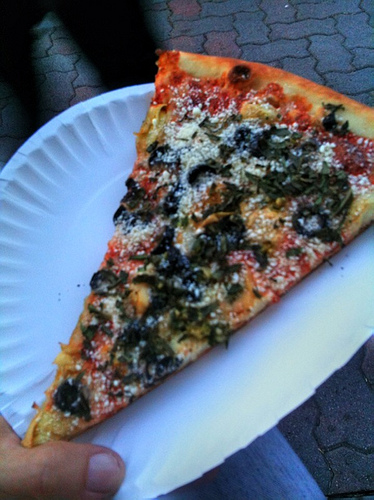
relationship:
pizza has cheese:
[70, 69, 360, 344] [169, 98, 237, 163]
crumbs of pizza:
[315, 246, 373, 278] [70, 69, 360, 344]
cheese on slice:
[169, 98, 237, 163] [131, 55, 276, 334]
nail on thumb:
[83, 450, 126, 492] [15, 419, 171, 491]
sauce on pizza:
[204, 64, 229, 100] [70, 69, 360, 344]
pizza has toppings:
[70, 69, 360, 344] [116, 127, 307, 322]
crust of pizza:
[198, 53, 333, 119] [70, 69, 360, 344]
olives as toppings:
[122, 178, 181, 224] [116, 127, 307, 322]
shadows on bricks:
[30, 23, 179, 64] [246, 14, 373, 75]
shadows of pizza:
[30, 23, 179, 64] [70, 69, 360, 344]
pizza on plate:
[70, 69, 360, 344] [14, 97, 108, 230]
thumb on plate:
[15, 419, 171, 491] [14, 97, 108, 230]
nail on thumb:
[83, 450, 158, 482] [15, 419, 171, 491]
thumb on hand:
[15, 419, 171, 491] [0, 418, 126, 495]